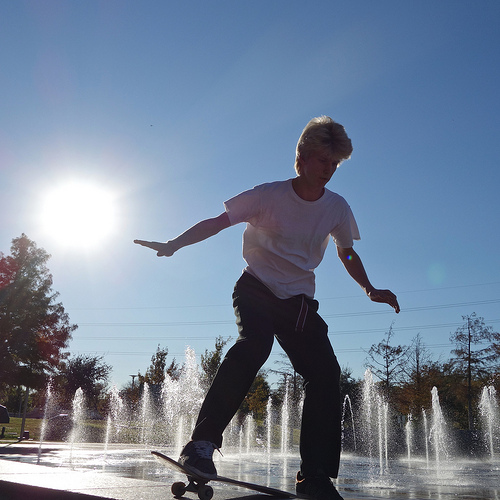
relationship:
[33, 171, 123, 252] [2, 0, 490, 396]
sun on sky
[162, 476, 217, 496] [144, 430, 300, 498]
wheels are on skateboard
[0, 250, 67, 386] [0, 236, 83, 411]
leaves are on tree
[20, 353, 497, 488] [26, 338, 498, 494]
water on fountain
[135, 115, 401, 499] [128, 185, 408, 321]
man has arms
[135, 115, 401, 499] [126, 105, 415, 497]
man on skateboard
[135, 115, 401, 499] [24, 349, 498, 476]
man near fountain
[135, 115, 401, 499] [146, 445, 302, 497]
man on skateboard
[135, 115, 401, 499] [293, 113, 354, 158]
man has hair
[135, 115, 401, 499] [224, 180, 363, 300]
man wears shirt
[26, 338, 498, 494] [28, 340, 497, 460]
fountain sprays water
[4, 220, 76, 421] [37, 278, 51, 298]
tree has leaves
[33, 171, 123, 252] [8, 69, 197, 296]
sun in sky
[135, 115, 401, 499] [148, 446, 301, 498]
man doing skateboard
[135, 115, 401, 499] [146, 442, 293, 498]
man on skateboard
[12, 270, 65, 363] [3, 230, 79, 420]
leaves on tree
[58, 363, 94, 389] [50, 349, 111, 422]
leaves on tree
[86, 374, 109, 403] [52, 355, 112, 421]
leaves on tree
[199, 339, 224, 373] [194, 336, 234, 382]
leaves on tree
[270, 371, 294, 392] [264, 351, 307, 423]
leaves on tree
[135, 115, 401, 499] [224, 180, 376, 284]
man wearing shirt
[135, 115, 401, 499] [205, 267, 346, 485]
man wearing pants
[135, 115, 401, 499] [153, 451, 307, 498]
man using skateboard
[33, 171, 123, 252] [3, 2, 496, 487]
sun in sky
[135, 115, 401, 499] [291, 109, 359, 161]
man has hair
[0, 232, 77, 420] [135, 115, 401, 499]
tree behind man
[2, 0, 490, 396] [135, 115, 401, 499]
sky behind man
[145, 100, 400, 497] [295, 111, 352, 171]
man has hair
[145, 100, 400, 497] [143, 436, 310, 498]
man riding skateboard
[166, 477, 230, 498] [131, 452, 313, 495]
wheels on skateboard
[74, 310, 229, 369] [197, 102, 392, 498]
power lines behind skater